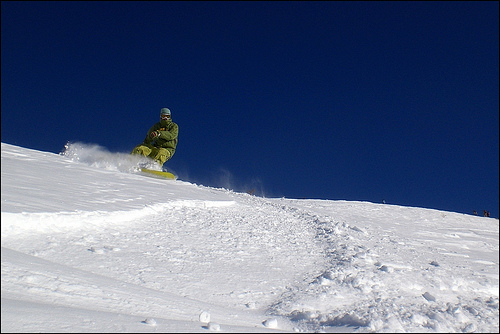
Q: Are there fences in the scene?
A: No, there are no fences.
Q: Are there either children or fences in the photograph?
A: No, there are no fences or children.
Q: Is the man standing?
A: Yes, the man is standing.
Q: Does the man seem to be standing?
A: Yes, the man is standing.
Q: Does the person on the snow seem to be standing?
A: Yes, the man is standing.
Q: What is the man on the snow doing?
A: The man is standing.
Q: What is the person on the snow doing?
A: The man is standing.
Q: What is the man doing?
A: The man is standing.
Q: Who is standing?
A: The man is standing.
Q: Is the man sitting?
A: No, the man is standing.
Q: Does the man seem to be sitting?
A: No, the man is standing.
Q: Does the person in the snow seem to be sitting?
A: No, the man is standing.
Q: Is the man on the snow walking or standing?
A: The man is standing.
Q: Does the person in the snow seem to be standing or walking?
A: The man is standing.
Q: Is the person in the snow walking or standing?
A: The man is standing.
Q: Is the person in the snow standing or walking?
A: The man is standing.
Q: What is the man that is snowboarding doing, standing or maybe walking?
A: The man is standing.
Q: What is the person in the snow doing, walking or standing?
A: The man is standing.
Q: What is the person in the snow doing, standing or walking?
A: The man is standing.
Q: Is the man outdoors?
A: Yes, the man is outdoors.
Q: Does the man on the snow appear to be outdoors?
A: Yes, the man is outdoors.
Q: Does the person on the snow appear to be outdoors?
A: Yes, the man is outdoors.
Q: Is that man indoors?
A: No, the man is outdoors.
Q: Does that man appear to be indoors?
A: No, the man is outdoors.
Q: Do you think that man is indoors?
A: No, the man is outdoors.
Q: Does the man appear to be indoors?
A: No, the man is outdoors.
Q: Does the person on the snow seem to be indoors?
A: No, the man is outdoors.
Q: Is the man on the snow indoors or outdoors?
A: The man is outdoors.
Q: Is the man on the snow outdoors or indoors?
A: The man is outdoors.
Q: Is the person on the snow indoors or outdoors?
A: The man is outdoors.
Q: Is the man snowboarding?
A: Yes, the man is snowboarding.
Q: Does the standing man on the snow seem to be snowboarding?
A: Yes, the man is snowboarding.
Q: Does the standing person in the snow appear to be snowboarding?
A: Yes, the man is snowboarding.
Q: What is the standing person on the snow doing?
A: The man is snowboarding.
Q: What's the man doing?
A: The man is snowboarding.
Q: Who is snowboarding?
A: The man is snowboarding.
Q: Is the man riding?
A: No, the man is snowboarding.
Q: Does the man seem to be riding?
A: No, the man is snowboarding.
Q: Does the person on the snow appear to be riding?
A: No, the man is snowboarding.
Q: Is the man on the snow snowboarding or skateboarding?
A: The man is snowboarding.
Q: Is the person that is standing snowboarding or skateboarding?
A: The man is snowboarding.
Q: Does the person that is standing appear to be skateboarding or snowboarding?
A: The man is snowboarding.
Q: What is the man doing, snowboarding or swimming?
A: The man is snowboarding.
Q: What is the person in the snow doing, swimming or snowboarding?
A: The man is snowboarding.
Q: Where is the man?
A: The man is in the snow.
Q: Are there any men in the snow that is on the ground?
A: Yes, there is a man in the snow.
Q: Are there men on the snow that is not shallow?
A: Yes, there is a man on the snow.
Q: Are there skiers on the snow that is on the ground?
A: No, there is a man on the snow.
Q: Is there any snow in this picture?
A: Yes, there is snow.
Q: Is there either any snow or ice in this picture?
A: Yes, there is snow.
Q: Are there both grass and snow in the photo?
A: No, there is snow but no grass.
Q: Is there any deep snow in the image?
A: Yes, there is deep snow.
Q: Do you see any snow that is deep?
A: Yes, there is snow that is deep.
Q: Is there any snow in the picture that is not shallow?
A: Yes, there is deep snow.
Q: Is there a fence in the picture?
A: No, there are no fences.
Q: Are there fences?
A: No, there are no fences.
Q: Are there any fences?
A: No, there are no fences.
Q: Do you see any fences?
A: No, there are no fences.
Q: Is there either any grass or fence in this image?
A: No, there are no fences or grass.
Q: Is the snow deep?
A: Yes, the snow is deep.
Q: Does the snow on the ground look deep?
A: Yes, the snow is deep.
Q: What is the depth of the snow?
A: The snow is deep.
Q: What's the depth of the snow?
A: The snow is deep.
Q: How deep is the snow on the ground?
A: The snow is deep.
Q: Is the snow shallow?
A: No, the snow is deep.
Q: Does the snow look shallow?
A: No, the snow is deep.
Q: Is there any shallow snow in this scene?
A: No, there is snow but it is deep.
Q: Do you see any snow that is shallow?
A: No, there is snow but it is deep.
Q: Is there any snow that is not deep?
A: No, there is snow but it is deep.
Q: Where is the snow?
A: The snow is on the ground.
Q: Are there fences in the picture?
A: No, there are no fences.